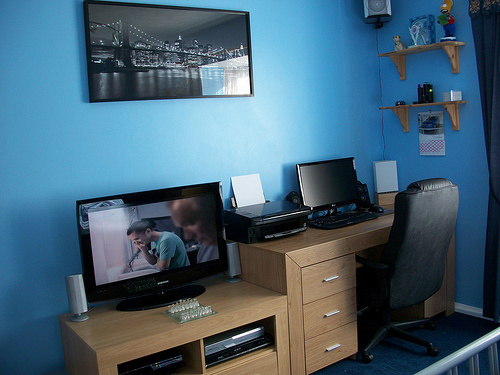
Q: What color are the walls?
A: Blue.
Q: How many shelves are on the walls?
A: Two.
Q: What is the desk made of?
A: Wood.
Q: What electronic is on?
A: TV.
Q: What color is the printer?
A: Black.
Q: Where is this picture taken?
A: Office space.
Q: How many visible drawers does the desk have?
A: Three.